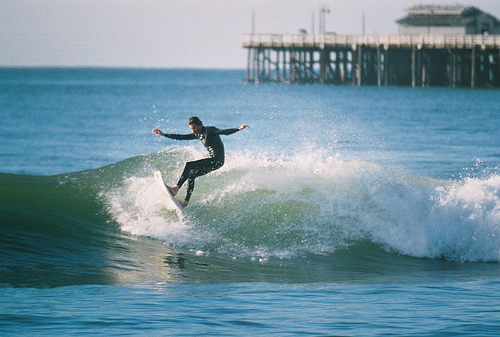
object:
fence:
[241, 33, 500, 53]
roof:
[394, 13, 472, 25]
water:
[1, 65, 500, 337]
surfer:
[148, 115, 250, 209]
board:
[151, 169, 188, 212]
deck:
[240, 33, 498, 85]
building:
[393, 2, 499, 35]